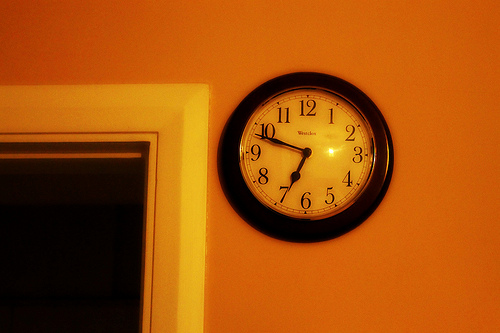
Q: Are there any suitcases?
A: No, there are no suitcases.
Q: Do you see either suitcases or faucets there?
A: No, there are no suitcases or faucets.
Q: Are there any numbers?
A: Yes, there are numbers.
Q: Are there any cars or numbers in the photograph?
A: Yes, there are numbers.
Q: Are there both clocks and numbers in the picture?
A: Yes, there are both numbers and a clock.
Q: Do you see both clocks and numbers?
A: Yes, there are both numbers and a clock.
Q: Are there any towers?
A: No, there are no towers.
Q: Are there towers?
A: No, there are no towers.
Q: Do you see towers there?
A: No, there are no towers.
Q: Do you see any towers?
A: No, there are no towers.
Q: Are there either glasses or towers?
A: No, there are no towers or glasses.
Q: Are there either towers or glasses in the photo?
A: No, there are no towers or glasses.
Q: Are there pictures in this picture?
A: No, there are no pictures.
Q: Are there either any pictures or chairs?
A: No, there are no pictures or chairs.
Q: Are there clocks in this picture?
A: Yes, there is a clock.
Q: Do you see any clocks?
A: Yes, there is a clock.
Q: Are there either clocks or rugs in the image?
A: Yes, there is a clock.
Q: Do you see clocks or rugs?
A: Yes, there is a clock.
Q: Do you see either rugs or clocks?
A: Yes, there is a clock.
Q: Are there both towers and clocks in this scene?
A: No, there is a clock but no towers.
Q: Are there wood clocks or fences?
A: Yes, there is a wood clock.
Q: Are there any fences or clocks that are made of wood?
A: Yes, the clock is made of wood.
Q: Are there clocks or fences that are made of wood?
A: Yes, the clock is made of wood.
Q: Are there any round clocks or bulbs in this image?
A: Yes, there is a round clock.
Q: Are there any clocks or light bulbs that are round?
A: Yes, the clock is round.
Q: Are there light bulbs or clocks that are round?
A: Yes, the clock is round.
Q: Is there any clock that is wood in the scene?
A: Yes, there is a wood clock.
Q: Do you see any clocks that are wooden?
A: Yes, there is a clock that is wooden.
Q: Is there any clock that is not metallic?
A: Yes, there is a wooden clock.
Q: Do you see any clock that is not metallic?
A: Yes, there is a wooden clock.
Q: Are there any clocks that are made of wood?
A: Yes, there is a clock that is made of wood.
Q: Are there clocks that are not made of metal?
A: Yes, there is a clock that is made of wood.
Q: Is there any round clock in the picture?
A: Yes, there is a round clock.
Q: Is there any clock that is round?
A: Yes, there is a clock that is round.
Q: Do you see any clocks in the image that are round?
A: Yes, there is a clock that is round.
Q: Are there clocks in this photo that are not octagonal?
A: Yes, there is an round clock.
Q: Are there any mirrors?
A: No, there are no mirrors.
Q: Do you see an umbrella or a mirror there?
A: No, there are no mirrors or umbrellas.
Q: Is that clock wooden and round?
A: Yes, the clock is wooden and round.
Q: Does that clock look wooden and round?
A: Yes, the clock is wooden and round.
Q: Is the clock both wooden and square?
A: No, the clock is wooden but round.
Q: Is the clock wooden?
A: Yes, the clock is wooden.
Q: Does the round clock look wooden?
A: Yes, the clock is wooden.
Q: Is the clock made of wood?
A: Yes, the clock is made of wood.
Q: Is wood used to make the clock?
A: Yes, the clock is made of wood.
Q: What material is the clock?
A: The clock is made of wood.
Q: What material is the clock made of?
A: The clock is made of wood.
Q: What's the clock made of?
A: The clock is made of wood.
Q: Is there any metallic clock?
A: No, there is a clock but it is wooden.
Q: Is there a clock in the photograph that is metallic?
A: No, there is a clock but it is wooden.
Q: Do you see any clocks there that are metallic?
A: No, there is a clock but it is wooden.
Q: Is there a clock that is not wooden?
A: No, there is a clock but it is wooden.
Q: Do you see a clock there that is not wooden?
A: No, there is a clock but it is wooden.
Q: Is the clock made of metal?
A: No, the clock is made of wood.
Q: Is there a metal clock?
A: No, there is a clock but it is made of wood.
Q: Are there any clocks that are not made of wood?
A: No, there is a clock but it is made of wood.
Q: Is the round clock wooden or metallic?
A: The clock is wooden.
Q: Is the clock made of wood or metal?
A: The clock is made of wood.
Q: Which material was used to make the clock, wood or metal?
A: The clock is made of wood.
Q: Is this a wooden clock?
A: Yes, this is a wooden clock.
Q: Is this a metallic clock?
A: No, this is a wooden clock.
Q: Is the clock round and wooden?
A: Yes, the clock is round and wooden.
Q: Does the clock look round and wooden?
A: Yes, the clock is round and wooden.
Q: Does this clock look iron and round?
A: No, the clock is round but wooden.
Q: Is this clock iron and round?
A: No, the clock is round but wooden.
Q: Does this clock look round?
A: Yes, the clock is round.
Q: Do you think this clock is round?
A: Yes, the clock is round.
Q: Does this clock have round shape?
A: Yes, the clock is round.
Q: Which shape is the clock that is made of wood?
A: The clock is round.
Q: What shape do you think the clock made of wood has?
A: The clock has round shape.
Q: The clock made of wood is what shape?
A: The clock is round.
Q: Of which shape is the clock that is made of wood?
A: The clock is round.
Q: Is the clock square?
A: No, the clock is round.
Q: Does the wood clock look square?
A: No, the clock is round.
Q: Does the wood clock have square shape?
A: No, the clock is round.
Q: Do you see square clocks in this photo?
A: No, there is a clock but it is round.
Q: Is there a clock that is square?
A: No, there is a clock but it is round.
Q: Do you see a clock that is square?
A: No, there is a clock but it is round.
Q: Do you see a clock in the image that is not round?
A: No, there is a clock but it is round.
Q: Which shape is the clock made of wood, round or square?
A: The clock is round.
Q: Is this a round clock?
A: Yes, this is a round clock.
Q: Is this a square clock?
A: No, this is a round clock.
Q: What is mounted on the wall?
A: The clock is mounted on the wall.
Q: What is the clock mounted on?
A: The clock is mounted on the wall.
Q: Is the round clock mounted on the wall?
A: Yes, the clock is mounted on the wall.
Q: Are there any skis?
A: No, there are no skis.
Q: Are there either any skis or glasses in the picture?
A: No, there are no skis or glasses.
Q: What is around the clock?
A: The frame is around the clock.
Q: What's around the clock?
A: The frame is around the clock.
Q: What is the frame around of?
A: The frame is around the clock.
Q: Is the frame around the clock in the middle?
A: Yes, the frame is around the clock.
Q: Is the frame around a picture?
A: No, the frame is around the clock.